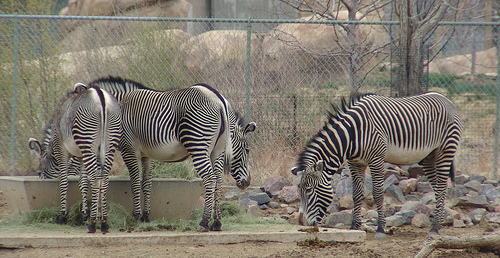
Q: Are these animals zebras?
A: Yes, all the animals are zebras.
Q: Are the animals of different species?
A: No, all the animals are zebras.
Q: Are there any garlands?
A: No, there are no garlands.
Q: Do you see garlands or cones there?
A: No, there are no garlands or cones.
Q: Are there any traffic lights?
A: No, there are no traffic lights.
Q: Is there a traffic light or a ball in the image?
A: No, there are no traffic lights or balls.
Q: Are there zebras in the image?
A: Yes, there is a zebra.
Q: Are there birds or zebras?
A: Yes, there is a zebra.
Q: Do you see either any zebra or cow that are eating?
A: Yes, the zebra is eating.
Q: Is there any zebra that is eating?
A: Yes, there is a zebra that is eating.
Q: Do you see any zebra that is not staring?
A: Yes, there is a zebra that is eating .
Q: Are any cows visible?
A: No, there are no cows.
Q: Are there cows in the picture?
A: No, there are no cows.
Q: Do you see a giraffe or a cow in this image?
A: No, there are no cows or giraffes.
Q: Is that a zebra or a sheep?
A: That is a zebra.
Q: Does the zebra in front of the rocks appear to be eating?
A: Yes, the zebra is eating.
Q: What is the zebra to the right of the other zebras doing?
A: The zebra is eating.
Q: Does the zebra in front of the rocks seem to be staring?
A: No, the zebra is eating.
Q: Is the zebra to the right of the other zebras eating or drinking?
A: The zebra is eating.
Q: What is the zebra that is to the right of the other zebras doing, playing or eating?
A: The zebra is eating.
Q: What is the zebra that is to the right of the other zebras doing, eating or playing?
A: The zebra is eating.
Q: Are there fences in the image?
A: Yes, there is a fence.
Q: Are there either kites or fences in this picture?
A: Yes, there is a fence.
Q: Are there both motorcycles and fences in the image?
A: No, there is a fence but no motorcycles.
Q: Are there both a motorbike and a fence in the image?
A: No, there is a fence but no motorcycles.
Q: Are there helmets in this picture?
A: No, there are no helmets.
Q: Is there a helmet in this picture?
A: No, there are no helmets.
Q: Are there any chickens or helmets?
A: No, there are no helmets or chickens.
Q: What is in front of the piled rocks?
A: The fence is in front of the rocks.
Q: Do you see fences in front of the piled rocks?
A: Yes, there is a fence in front of the rocks.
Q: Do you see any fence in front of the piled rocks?
A: Yes, there is a fence in front of the rocks.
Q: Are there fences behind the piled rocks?
A: No, the fence is in front of the rocks.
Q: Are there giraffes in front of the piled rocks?
A: No, there is a fence in front of the rocks.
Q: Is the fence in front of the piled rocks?
A: Yes, the fence is in front of the rocks.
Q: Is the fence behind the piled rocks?
A: No, the fence is in front of the rocks.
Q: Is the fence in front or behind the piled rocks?
A: The fence is in front of the rocks.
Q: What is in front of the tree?
A: The fence is in front of the tree.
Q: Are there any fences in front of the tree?
A: Yes, there is a fence in front of the tree.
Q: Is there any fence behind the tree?
A: No, the fence is in front of the tree.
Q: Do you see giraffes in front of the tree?
A: No, there is a fence in front of the tree.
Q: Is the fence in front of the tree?
A: Yes, the fence is in front of the tree.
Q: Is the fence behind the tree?
A: No, the fence is in front of the tree.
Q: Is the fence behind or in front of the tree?
A: The fence is in front of the tree.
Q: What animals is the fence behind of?
A: The fence is behind the zebras.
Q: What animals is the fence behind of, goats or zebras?
A: The fence is behind zebras.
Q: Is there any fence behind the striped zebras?
A: Yes, there is a fence behind the zebras.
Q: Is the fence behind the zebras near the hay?
A: Yes, the fence is behind the zebras.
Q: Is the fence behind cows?
A: No, the fence is behind the zebras.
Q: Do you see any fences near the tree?
A: Yes, there is a fence near the tree.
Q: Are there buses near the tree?
A: No, there is a fence near the tree.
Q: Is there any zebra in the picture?
A: Yes, there are zebras.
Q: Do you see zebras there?
A: Yes, there are zebras.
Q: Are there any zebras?
A: Yes, there are zebras.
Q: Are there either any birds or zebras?
A: Yes, there are zebras.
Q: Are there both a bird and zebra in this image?
A: No, there are zebras but no birds.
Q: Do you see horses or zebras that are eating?
A: Yes, the zebras are eating.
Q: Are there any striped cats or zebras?
A: Yes, there are striped zebras.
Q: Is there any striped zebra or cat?
A: Yes, there are striped zebras.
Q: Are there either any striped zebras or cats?
A: Yes, there are striped zebras.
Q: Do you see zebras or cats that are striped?
A: Yes, the zebras are striped.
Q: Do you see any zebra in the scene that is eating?
A: Yes, there are zebras that are eating.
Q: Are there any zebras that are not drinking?
A: Yes, there are zebras that are eating.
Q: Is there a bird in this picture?
A: No, there are no birds.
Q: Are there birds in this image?
A: No, there are no birds.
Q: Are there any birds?
A: No, there are no birds.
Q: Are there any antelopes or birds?
A: No, there are no birds or antelopes.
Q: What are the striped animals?
A: The animals are zebras.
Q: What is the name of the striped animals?
A: The animals are zebras.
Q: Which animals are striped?
A: The animals are zebras.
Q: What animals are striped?
A: The animals are zebras.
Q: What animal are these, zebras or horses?
A: These are zebras.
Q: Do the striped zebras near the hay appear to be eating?
A: Yes, the zebras are eating.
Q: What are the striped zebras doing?
A: The zebras are eating.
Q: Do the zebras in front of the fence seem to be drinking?
A: No, the zebras are eating.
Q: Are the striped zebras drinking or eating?
A: The zebras are eating.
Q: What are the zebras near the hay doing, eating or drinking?
A: The zebras are eating.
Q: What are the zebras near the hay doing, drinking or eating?
A: The zebras are eating.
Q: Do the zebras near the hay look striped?
A: Yes, the zebras are striped.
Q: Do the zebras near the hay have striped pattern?
A: Yes, the zebras are striped.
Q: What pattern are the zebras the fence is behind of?
A: The zebras are striped.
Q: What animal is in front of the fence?
A: The zebras are in front of the fence.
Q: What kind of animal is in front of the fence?
A: The animals are zebras.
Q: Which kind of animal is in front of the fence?
A: The animals are zebras.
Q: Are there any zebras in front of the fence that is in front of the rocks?
A: Yes, there are zebras in front of the fence.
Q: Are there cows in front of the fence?
A: No, there are zebras in front of the fence.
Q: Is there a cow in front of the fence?
A: No, there are zebras in front of the fence.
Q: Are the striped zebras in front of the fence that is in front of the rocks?
A: Yes, the zebras are in front of the fence.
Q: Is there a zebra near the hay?
A: Yes, there are zebras near the hay.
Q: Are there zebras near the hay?
A: Yes, there are zebras near the hay.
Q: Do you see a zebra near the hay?
A: Yes, there are zebras near the hay.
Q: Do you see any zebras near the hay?
A: Yes, there are zebras near the hay.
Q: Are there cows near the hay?
A: No, there are zebras near the hay.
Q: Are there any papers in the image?
A: No, there are no papers.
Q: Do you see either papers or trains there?
A: No, there are no papers or trains.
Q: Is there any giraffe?
A: No, there are no giraffes.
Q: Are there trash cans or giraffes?
A: No, there are no giraffes or trash cans.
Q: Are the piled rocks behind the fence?
A: Yes, the rocks are behind the fence.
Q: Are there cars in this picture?
A: No, there are no cars.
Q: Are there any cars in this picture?
A: No, there are no cars.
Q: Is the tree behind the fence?
A: Yes, the tree is behind the fence.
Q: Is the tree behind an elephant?
A: No, the tree is behind the fence.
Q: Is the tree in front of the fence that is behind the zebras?
A: No, the tree is behind the fence.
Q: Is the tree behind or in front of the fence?
A: The tree is behind the fence.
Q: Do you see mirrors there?
A: No, there are no mirrors.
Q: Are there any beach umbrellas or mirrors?
A: No, there are no mirrors or beach umbrellas.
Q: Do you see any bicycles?
A: No, there are no bicycles.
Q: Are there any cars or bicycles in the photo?
A: No, there are no bicycles or cars.